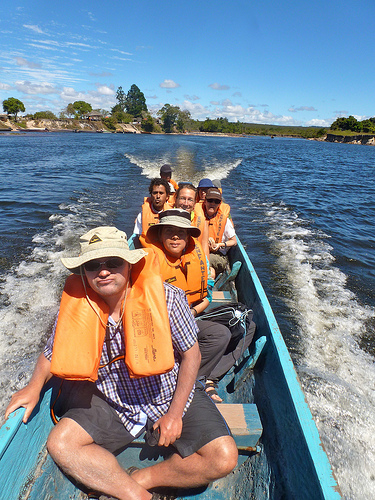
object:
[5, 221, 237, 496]
man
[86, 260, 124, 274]
sunglasses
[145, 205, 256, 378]
woman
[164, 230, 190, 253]
expression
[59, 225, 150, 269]
hat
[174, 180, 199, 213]
person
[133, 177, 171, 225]
man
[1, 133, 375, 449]
canoe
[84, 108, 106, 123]
tent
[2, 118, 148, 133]
shore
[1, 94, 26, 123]
tree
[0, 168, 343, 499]
boat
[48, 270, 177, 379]
lifevest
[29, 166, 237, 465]
people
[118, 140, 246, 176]
waves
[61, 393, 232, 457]
shorts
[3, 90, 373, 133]
trees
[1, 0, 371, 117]
sky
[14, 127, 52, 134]
dock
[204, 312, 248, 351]
bag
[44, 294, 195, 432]
plaid shirt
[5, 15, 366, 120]
clouds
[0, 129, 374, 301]
river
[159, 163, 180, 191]
person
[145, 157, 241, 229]
back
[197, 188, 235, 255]
person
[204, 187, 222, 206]
brown hat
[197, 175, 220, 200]
person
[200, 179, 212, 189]
blue hat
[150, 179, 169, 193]
black hair